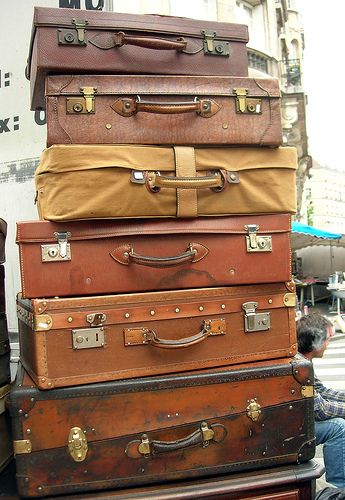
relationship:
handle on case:
[110, 34, 198, 56] [34, 144, 298, 219]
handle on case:
[135, 324, 233, 350] [16, 278, 295, 386]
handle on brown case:
[130, 427, 210, 456] [5, 357, 316, 475]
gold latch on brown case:
[67, 423, 89, 459] [5, 357, 316, 475]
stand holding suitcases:
[48, 456, 324, 498] [5, 3, 329, 498]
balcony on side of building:
[241, 13, 283, 84] [0, 1, 311, 201]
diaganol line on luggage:
[16, 396, 311, 452] [4, 350, 313, 497]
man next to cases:
[299, 313, 344, 489] [15, 210, 298, 385]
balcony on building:
[274, 54, 309, 99] [1, 0, 340, 341]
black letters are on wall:
[60, 0, 110, 13] [0, 0, 113, 303]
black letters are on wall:
[2, 106, 48, 133] [0, 0, 113, 303]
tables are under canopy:
[296, 276, 319, 308] [288, 219, 341, 300]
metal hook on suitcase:
[67, 327, 108, 353] [17, 290, 296, 388]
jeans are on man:
[307, 415, 343, 489] [299, 313, 344, 489]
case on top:
[14, 4, 248, 75] [18, 6, 274, 124]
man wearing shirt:
[299, 313, 344, 489] [295, 349, 344, 419]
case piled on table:
[14, 4, 248, 75] [0, 227, 16, 360]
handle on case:
[135, 429, 220, 461] [9, 356, 306, 474]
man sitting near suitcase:
[299, 313, 344, 489] [26, 5, 252, 76]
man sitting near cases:
[299, 313, 344, 489] [46, 74, 285, 146]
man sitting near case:
[299, 313, 344, 489] [34, 144, 298, 219]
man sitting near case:
[299, 313, 344, 489] [16, 278, 295, 386]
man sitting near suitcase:
[299, 313, 344, 489] [32, 282, 297, 389]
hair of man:
[295, 313, 324, 353] [294, 314, 343, 498]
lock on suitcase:
[70, 310, 107, 349] [15, 280, 305, 390]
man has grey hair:
[299, 313, 344, 489] [310, 327, 323, 350]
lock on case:
[56, 24, 86, 44] [14, 4, 248, 75]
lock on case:
[201, 37, 229, 56] [14, 4, 248, 75]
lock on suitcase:
[234, 95, 262, 112] [38, 69, 290, 148]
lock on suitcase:
[63, 97, 95, 113] [38, 69, 290, 148]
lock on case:
[245, 235, 273, 254] [16, 278, 295, 386]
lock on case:
[38, 243, 72, 264] [16, 278, 295, 386]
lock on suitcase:
[243, 312, 271, 332] [13, 275, 298, 382]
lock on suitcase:
[70, 313, 108, 350] [13, 275, 298, 382]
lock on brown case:
[246, 398, 261, 421] [5, 357, 316, 475]